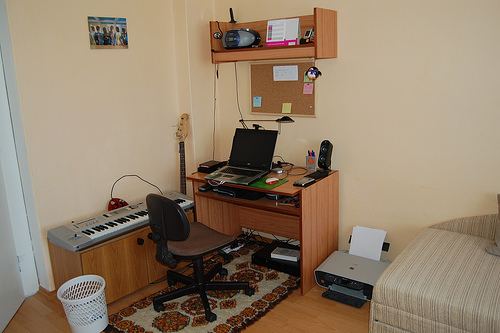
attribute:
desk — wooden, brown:
[188, 151, 346, 289]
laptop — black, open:
[207, 122, 281, 188]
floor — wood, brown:
[13, 239, 378, 332]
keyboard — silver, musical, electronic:
[43, 187, 194, 255]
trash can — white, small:
[52, 271, 120, 332]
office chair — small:
[146, 195, 258, 322]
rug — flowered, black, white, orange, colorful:
[115, 229, 300, 332]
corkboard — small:
[246, 64, 317, 122]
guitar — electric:
[174, 111, 197, 198]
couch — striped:
[364, 218, 499, 326]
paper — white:
[346, 229, 383, 262]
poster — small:
[84, 16, 129, 54]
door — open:
[2, 74, 41, 329]